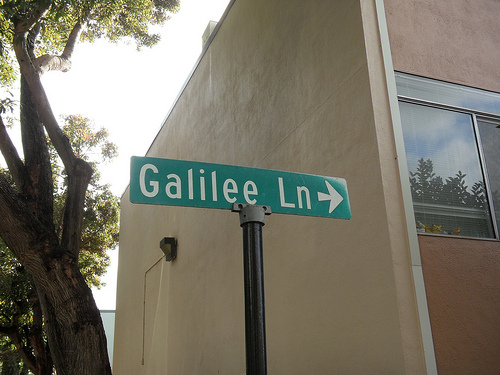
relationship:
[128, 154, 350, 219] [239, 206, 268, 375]
sign on metal pole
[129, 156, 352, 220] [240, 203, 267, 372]
sign on a pole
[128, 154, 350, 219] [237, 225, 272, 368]
sign on pole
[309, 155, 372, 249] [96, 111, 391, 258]
arrow on sign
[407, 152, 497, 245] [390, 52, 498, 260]
tree refected in window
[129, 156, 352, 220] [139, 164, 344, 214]
sign with letters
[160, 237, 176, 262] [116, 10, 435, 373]
holder on apartment wall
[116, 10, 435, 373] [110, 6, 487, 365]
wall of apartment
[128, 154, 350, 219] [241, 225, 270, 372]
sign on a pole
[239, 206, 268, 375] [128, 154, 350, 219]
metal pole with sign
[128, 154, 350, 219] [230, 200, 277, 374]
sign attached to pole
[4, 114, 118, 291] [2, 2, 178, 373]
leaves on tree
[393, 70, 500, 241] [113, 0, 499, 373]
window on building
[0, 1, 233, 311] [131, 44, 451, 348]
sky behind building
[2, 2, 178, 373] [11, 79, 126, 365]
tree has trunk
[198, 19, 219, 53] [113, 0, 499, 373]
unit on top of building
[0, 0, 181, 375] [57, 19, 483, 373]
tree next to building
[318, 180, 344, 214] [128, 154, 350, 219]
arrow printed on sign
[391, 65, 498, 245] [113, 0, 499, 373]
window on building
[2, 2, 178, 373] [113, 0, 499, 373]
tree next to building